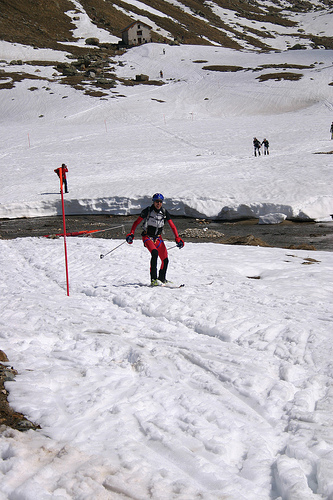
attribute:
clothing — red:
[125, 204, 184, 280]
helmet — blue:
[152, 191, 164, 201]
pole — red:
[58, 167, 70, 296]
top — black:
[138, 203, 172, 238]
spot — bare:
[245, 274, 260, 280]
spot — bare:
[283, 258, 291, 262]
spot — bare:
[285, 253, 295, 257]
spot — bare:
[301, 260, 313, 266]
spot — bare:
[302, 257, 321, 263]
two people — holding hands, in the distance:
[249, 135, 271, 155]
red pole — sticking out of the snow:
[55, 164, 72, 297]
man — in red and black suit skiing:
[125, 193, 186, 288]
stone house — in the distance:
[120, 18, 155, 48]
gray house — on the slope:
[120, 17, 152, 47]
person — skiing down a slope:
[122, 189, 184, 292]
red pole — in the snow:
[58, 165, 71, 297]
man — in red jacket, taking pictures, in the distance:
[54, 162, 69, 193]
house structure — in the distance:
[120, 19, 152, 45]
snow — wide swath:
[34, 250, 270, 412]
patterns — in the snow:
[116, 291, 304, 386]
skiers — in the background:
[251, 135, 270, 155]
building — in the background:
[119, 18, 153, 46]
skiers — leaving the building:
[158, 41, 167, 83]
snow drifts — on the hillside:
[129, 39, 319, 112]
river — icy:
[8, 208, 328, 252]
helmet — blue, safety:
[150, 190, 167, 204]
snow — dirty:
[4, 234, 327, 492]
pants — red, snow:
[140, 232, 169, 284]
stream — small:
[6, 211, 329, 250]